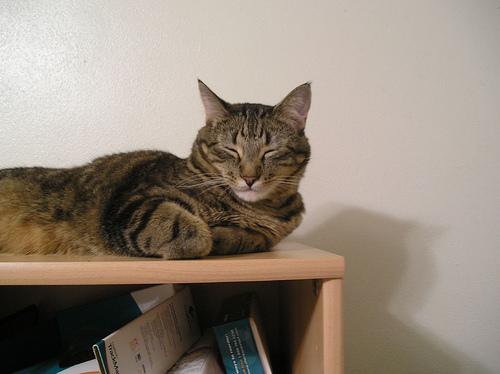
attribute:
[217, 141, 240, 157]
eye — closed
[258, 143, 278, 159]
eye — closed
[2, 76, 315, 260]
cat — sleeping, striped, brown, black, tabby, one, gray, relaxed, contented 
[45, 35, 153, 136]
wall — white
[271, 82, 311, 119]
ear — pink, feline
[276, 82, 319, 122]
ear — feline, hairy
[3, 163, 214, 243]
body — furry, feline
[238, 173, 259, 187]
nose — feline, pink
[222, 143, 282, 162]
eyes — feline, closed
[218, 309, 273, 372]
box — blue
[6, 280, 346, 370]
shelf — one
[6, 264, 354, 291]
shelf — wooden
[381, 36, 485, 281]
wall — beige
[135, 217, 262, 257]
paws — curled, feline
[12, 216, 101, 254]
belly — feline, fat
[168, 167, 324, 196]
whiskers — white, feline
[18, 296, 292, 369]
books — some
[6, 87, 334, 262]
cat — one, sleeping, striped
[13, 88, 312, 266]
cat — striped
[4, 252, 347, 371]
bookcase — wooden, pale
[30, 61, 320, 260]
cat — striped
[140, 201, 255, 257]
paws — curled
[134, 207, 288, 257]
cat paws — striped 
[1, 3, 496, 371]
white wall — White 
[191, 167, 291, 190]
white whiskers — White 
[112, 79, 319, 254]
black stripes — Black 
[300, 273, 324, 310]
metal bracket — Silver , metal 